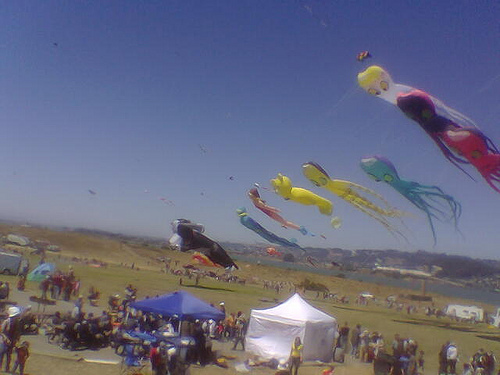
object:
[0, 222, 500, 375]
ground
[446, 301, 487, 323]
camper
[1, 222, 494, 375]
field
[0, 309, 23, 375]
person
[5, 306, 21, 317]
hat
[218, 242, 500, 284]
mountainside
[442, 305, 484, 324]
white building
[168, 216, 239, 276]
dog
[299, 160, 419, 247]
kite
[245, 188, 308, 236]
kite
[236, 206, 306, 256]
kite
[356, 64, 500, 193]
kite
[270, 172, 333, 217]
kite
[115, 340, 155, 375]
chair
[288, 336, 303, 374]
woman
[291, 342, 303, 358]
shirt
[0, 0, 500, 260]
blue sky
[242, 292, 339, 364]
tent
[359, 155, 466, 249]
kite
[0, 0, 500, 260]
skies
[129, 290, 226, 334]
tent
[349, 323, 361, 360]
people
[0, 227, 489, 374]
bench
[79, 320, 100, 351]
people sitting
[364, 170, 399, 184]
yellow eyes